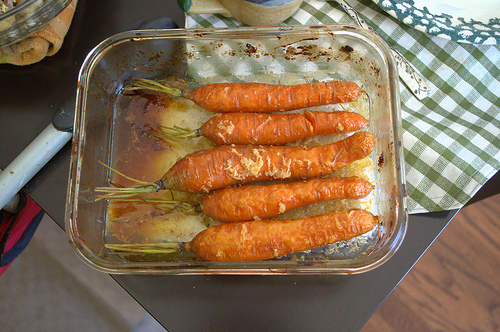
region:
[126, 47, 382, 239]
Carrot kept in the glass plate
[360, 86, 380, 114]
Main root of the carrot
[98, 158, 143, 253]
Terminal bud of the carrot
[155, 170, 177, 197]
Short stem of the carrot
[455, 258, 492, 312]
Wooden type floor tiles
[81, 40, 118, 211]
Glass plate kept above the table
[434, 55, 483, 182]
Green and white color checkered table cloth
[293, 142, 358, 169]
Lateral root of the carrot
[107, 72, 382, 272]
Orange color carrot with stem and root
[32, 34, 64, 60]
Towel near the glass plate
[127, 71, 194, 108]
the stems on a carrot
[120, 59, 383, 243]
baked carrots in a dish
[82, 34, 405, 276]
a glass baking dish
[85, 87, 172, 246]
liquid in a baking dish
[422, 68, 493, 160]
a green and white place mat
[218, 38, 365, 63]
baked on food on a dish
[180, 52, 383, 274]
five carrots in a dish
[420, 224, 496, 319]
wood grain pattern on a floor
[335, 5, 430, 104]
the metal handle of a cooking utensil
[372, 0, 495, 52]
a white plate with green design around the rim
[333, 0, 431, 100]
Utensil on a table cloth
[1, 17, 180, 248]
Knife on a cutting board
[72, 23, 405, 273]
Five carrots in a glass dish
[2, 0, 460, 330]
Cutting board on a counter top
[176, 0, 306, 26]
Ceramic mug on a cloth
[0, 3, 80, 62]
Folded towel under a glass dish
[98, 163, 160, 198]
Green top of a carrot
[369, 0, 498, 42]
Plate on a table cloth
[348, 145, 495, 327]
Wooden table under a cutting board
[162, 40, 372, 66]
Bits cooked to the edge of a glass dish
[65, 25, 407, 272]
whole carrots baked in pyrex baking dish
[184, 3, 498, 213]
green and white checked kitchen towel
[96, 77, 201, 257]
tops of carrots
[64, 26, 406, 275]
rectangular pyrex baking dish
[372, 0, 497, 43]
blue and white bowl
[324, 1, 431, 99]
silverware handle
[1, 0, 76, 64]
rolled up kitchen towel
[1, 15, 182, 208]
kitchen serving utensil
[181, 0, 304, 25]
glazed pottery cup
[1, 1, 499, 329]
dinner prep baked carrots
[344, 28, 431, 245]
Dish sitting near green and white place mat.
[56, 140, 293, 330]
Dish sitting on top of gray table.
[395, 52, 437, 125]
Silver utensil sitting on table.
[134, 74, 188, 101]
End of carrot has green on it.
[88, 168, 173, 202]
End of carrot has green on it.